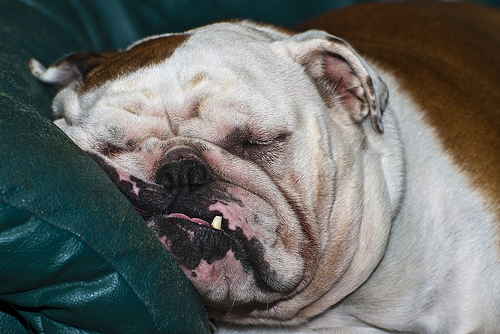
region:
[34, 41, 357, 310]
the dog is sleeping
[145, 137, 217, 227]
dog's nose is black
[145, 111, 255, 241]
dog's nose is black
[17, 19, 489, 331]
a bull dog on a pillow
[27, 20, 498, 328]
a bull dog laying down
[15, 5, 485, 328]
a bull dog sleeping on a pillow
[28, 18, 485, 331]
a bull dog taking a nap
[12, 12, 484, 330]
a bull dog resting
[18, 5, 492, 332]
a dog laying down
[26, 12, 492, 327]
a dog taking a nap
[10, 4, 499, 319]
a dog sleeping on a pillow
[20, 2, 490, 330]
a dog resting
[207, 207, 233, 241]
a dog with his tooth sticking out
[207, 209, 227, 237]
tooth sticking out of the dog's mouth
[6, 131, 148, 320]
green couch cushion dog is sleeping on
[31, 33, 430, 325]
sleeping dog on couch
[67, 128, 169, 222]
dog lip pulled up against cushion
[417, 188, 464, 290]
white fur on the dog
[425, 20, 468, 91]
brown fur on the dog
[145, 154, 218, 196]
black nose on the dog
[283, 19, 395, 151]
ear folded down on the dog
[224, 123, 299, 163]
closed eye of the dog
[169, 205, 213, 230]
dog's tongue sticking out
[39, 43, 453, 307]
The dog is sleep on the couch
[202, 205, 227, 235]
The tooth of the dog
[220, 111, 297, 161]
The eye of the dog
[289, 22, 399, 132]
The ear of the dog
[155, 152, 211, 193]
The nose of the dog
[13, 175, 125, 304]
The couch is the color green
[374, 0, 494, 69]
The dog is the color brown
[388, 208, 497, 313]
The dog is the color white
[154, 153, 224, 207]
The nose of the dog is black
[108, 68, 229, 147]
The forehead of the dog is wrinkled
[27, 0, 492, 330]
brown and white bull dog sleeping on green cushion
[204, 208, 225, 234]
white broken bull dog tooth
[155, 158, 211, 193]
black bulldoog nose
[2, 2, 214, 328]
green sofa cushion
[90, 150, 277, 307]
pink and brown snout of bulldog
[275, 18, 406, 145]
limp brown and white spotted bulldog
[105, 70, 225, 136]
wrinkled furrow on bull dog forehead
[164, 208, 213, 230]
pink bulldog tongue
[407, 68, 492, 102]
brown fur of bulldog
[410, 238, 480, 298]
white bulldog fur